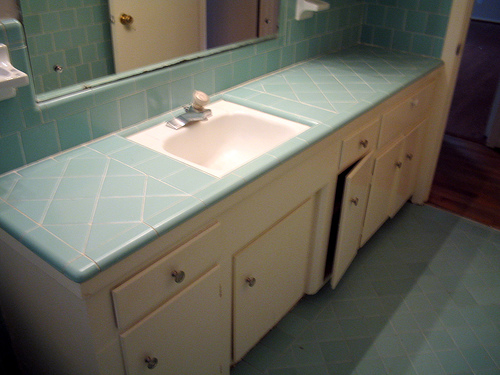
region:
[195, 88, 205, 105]
The knob of the sink.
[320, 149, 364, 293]
The open cabinet door.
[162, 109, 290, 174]
The basin of the sink.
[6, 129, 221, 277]
The counter on the left side of the sink.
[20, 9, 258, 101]
The mirror above the sink.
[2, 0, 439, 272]
blue tiles with white grout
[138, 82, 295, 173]
white sink in the countertop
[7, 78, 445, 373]
white cabinets under the sink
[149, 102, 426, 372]
silver knobs on white cabinets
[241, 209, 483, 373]
shadows on the floor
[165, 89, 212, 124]
faucet and handle on sink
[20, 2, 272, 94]
mirror above the sink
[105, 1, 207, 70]
door reflected in mirror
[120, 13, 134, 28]
door knob reflected in mirror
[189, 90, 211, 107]
The knob of the sink.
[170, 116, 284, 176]
The basin of the sink.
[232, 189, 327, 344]
The cabinet door in the middle.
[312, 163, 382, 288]
The open cabinet door.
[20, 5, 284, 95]
The mirror above the sink.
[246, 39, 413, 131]
The counter of the sink area on the right.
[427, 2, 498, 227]
The open doorway in the bathroom.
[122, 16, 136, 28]
The door knob on the door.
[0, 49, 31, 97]
The toothbrush holder on the left.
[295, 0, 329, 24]
The toothbrush holder on the right.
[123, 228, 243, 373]
white drawers on sink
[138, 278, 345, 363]
brown cabinets under sink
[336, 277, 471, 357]
green tile on floor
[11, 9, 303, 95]
mirror is above sink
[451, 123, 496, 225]
red carpet outside bathroom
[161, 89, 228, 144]
dull nickel finish on faucet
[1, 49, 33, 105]
white soap dish near mirror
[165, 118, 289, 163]
the sink is pink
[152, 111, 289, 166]
the sink is dated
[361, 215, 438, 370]
shadow on the floor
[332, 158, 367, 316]
the cabinet is open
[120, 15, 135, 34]
the handle is golden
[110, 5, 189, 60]
handle on the door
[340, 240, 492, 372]
the floor is tiled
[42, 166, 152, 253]
pink lines on the counter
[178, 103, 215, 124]
the faucet is silver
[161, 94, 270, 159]
faucet is on the sink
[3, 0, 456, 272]
blue ceramic tiled counter and backsplash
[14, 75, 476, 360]
white wooden bathroom cabinets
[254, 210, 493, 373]
blue tiled floor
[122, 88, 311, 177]
white sink with single knob faucet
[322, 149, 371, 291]
white cabinet door ajar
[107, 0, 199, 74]
reflection of a white door with gold handle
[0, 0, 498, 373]
bathroom with blue tiled counters and floor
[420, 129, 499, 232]
dark brown wood floor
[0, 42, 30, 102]
white toothbrush holder mounted on wall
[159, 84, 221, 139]
A bathroom faucet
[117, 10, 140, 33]
A bathroom doorknob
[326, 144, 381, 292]
An open bathroom cabinet door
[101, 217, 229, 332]
a bathroom cabinet drawer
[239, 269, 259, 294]
A knob of a bathroom cabinet door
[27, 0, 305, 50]
A mirror on the wall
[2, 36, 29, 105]
A white toothbrush holder on the wall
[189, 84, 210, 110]
The white handle on A bathroom faucet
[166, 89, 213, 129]
faucet is above sink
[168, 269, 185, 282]
knob is attached to the drawer